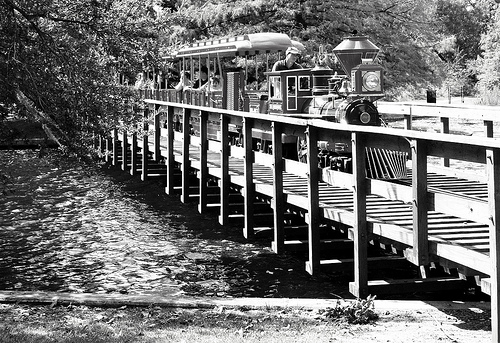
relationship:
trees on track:
[0, 0, 167, 160] [170, 116, 482, 216]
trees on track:
[374, 4, 499, 100] [170, 116, 482, 216]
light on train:
[366, 71, 381, 94] [122, 42, 397, 171]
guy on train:
[271, 38, 303, 74] [127, 29, 423, 189]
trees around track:
[318, 0, 498, 70] [170, 116, 500, 232]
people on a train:
[140, 55, 267, 85] [127, 29, 423, 189]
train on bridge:
[95, 30, 417, 182] [75, 81, 496, 339]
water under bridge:
[32, 207, 177, 272] [104, 82, 496, 262]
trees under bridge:
[4, 3, 498, 118] [80, 91, 498, 299]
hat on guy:
[282, 43, 302, 58] [272, 46, 305, 73]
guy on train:
[272, 46, 305, 73] [112, 25, 412, 185]